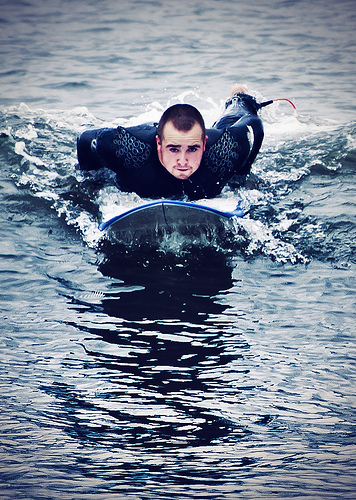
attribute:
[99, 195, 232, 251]
surfboard — lined, white, blue, grooved, silver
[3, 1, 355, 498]
water — blue, calm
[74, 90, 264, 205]
man — laying, riding, looking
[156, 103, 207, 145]
hair — short, dark, brown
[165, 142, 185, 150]
brow — dark, thick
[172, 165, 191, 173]
mouth — closed